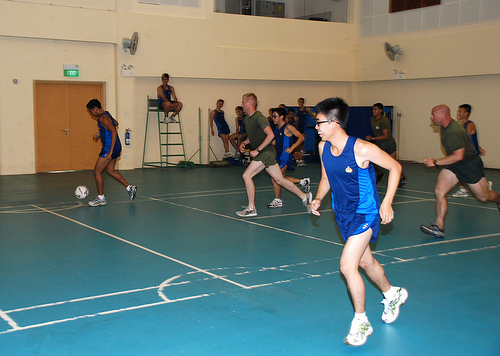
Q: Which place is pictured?
A: It is a gym.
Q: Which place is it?
A: It is a gym.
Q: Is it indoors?
A: Yes, it is indoors.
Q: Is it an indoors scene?
A: Yes, it is indoors.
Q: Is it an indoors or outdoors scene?
A: It is indoors.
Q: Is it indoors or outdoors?
A: It is indoors.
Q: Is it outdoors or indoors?
A: It is indoors.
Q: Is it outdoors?
A: No, it is indoors.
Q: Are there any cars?
A: No, there are no cars.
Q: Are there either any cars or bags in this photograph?
A: No, there are no cars or bags.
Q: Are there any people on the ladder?
A: Yes, there is a person on the ladder.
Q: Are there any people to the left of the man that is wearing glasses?
A: Yes, there is a person to the left of the man.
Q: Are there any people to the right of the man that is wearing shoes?
A: No, the person is to the left of the man.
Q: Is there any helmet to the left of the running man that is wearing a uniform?
A: No, there is a person to the left of the man.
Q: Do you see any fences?
A: No, there are no fences.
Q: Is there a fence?
A: No, there are no fences.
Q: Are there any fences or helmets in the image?
A: No, there are no fences or helmets.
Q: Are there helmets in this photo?
A: No, there are no helmets.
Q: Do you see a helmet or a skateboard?
A: No, there are no helmets or skateboards.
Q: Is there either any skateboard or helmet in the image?
A: No, there are no helmets or skateboards.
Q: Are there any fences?
A: No, there are no fences.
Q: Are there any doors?
A: Yes, there are doors.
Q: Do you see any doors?
A: Yes, there are doors.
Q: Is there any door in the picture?
A: Yes, there are doors.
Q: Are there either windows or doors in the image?
A: Yes, there are doors.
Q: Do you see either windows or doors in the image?
A: Yes, there are doors.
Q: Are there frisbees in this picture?
A: No, there are no frisbees.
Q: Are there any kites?
A: No, there are no kites.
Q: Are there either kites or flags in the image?
A: No, there are no kites or flags.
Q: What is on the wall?
A: The fan is on the wall.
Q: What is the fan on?
A: The fan is on the wall.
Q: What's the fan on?
A: The fan is on the wall.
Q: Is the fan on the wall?
A: Yes, the fan is on the wall.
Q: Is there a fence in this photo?
A: No, there are no fences.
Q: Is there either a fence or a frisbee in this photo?
A: No, there are no fences or frisbees.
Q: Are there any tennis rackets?
A: No, there are no tennis rackets.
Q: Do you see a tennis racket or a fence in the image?
A: No, there are no rackets or fences.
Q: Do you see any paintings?
A: No, there are no paintings.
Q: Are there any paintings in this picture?
A: No, there are no paintings.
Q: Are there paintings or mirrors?
A: No, there are no paintings or mirrors.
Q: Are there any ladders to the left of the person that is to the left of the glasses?
A: Yes, there is a ladder to the left of the person.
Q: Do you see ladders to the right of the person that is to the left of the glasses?
A: No, the ladder is to the left of the person.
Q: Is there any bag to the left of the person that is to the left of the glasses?
A: No, there is a ladder to the left of the person.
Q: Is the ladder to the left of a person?
A: Yes, the ladder is to the left of a person.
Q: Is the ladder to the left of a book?
A: No, the ladder is to the left of a person.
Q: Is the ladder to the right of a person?
A: No, the ladder is to the left of a person.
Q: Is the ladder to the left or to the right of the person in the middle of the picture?
A: The ladder is to the left of the person.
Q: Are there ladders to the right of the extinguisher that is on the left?
A: Yes, there is a ladder to the right of the fire extinguisher.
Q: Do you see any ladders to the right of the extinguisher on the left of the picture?
A: Yes, there is a ladder to the right of the fire extinguisher.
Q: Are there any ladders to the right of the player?
A: Yes, there is a ladder to the right of the player.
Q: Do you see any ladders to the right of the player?
A: Yes, there is a ladder to the right of the player.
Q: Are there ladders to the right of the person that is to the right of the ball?
A: Yes, there is a ladder to the right of the player.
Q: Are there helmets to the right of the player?
A: No, there is a ladder to the right of the player.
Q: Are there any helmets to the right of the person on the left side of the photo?
A: No, there is a ladder to the right of the player.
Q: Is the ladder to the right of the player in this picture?
A: Yes, the ladder is to the right of the player.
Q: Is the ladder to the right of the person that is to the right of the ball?
A: Yes, the ladder is to the right of the player.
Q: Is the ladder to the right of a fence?
A: No, the ladder is to the right of the player.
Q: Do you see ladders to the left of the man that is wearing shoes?
A: Yes, there is a ladder to the left of the man.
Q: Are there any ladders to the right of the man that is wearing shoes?
A: No, the ladder is to the left of the man.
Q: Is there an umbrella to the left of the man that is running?
A: No, there is a ladder to the left of the man.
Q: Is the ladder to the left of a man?
A: Yes, the ladder is to the left of a man.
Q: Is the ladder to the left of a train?
A: No, the ladder is to the left of a man.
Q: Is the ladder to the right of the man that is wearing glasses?
A: No, the ladder is to the left of the man.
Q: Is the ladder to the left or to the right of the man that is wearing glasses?
A: The ladder is to the left of the man.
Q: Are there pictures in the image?
A: No, there are no pictures.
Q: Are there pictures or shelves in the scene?
A: No, there are no pictures or shelves.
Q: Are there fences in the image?
A: No, there are no fences.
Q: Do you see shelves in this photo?
A: No, there are no shelves.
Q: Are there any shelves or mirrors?
A: No, there are no shelves or mirrors.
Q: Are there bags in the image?
A: No, there are no bags.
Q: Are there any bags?
A: No, there are no bags.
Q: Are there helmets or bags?
A: No, there are no bags or helmets.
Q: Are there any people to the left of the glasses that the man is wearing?
A: Yes, there is a person to the left of the glasses.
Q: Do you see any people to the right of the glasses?
A: No, the person is to the left of the glasses.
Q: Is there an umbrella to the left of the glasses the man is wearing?
A: No, there is a person to the left of the glasses.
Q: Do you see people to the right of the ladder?
A: Yes, there is a person to the right of the ladder.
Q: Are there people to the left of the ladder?
A: No, the person is to the right of the ladder.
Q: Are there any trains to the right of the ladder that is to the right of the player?
A: No, there is a person to the right of the ladder.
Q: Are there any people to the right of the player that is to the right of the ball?
A: Yes, there is a person to the right of the player.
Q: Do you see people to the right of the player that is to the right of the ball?
A: Yes, there is a person to the right of the player.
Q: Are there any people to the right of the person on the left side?
A: Yes, there is a person to the right of the player.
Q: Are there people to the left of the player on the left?
A: No, the person is to the right of the player.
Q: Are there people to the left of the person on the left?
A: No, the person is to the right of the player.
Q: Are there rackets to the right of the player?
A: No, there is a person to the right of the player.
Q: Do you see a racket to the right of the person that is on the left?
A: No, there is a person to the right of the player.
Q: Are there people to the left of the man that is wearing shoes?
A: Yes, there is a person to the left of the man.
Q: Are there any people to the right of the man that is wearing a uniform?
A: No, the person is to the left of the man.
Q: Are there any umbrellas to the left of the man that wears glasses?
A: No, there is a person to the left of the man.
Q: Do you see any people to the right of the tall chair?
A: Yes, there is a person to the right of the chair.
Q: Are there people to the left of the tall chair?
A: No, the person is to the right of the chair.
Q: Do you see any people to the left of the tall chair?
A: No, the person is to the right of the chair.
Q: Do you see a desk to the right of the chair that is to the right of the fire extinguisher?
A: No, there is a person to the right of the chair.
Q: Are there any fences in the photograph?
A: No, there are no fences.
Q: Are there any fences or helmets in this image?
A: No, there are no fences or helmets.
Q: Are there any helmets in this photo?
A: No, there are no helmets.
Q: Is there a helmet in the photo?
A: No, there are no helmets.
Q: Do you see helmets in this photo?
A: No, there are no helmets.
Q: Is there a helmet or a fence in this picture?
A: No, there are no helmets or fences.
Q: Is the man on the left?
A: No, the man is on the right of the image.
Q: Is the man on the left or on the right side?
A: The man is on the right of the image.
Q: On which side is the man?
A: The man is on the right of the image.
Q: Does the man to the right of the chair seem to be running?
A: Yes, the man is running.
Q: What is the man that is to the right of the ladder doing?
A: The man is running.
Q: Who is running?
A: The man is running.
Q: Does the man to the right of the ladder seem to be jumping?
A: No, the man is running.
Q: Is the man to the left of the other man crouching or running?
A: The man is running.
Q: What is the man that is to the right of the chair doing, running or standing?
A: The man is running.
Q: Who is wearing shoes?
A: The man is wearing shoes.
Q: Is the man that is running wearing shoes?
A: Yes, the man is wearing shoes.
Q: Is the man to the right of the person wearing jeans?
A: No, the man is wearing shoes.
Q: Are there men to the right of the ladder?
A: Yes, there is a man to the right of the ladder.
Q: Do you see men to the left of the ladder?
A: No, the man is to the right of the ladder.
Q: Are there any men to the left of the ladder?
A: No, the man is to the right of the ladder.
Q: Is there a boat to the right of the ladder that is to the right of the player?
A: No, there is a man to the right of the ladder.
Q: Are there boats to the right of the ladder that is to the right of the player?
A: No, there is a man to the right of the ladder.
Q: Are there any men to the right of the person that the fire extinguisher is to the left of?
A: Yes, there is a man to the right of the person.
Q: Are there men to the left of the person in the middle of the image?
A: No, the man is to the right of the person.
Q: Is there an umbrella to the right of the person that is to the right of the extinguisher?
A: No, there is a man to the right of the person.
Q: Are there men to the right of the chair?
A: Yes, there is a man to the right of the chair.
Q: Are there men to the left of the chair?
A: No, the man is to the right of the chair.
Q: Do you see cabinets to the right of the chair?
A: No, there is a man to the right of the chair.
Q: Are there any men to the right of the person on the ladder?
A: Yes, there is a man to the right of the person.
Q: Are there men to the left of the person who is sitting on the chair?
A: No, the man is to the right of the person.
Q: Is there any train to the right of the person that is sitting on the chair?
A: No, there is a man to the right of the person.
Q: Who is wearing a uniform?
A: The man is wearing a uniform.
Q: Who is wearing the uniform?
A: The man is wearing a uniform.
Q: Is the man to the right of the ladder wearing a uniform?
A: Yes, the man is wearing a uniform.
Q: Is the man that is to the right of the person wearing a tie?
A: No, the man is wearing a uniform.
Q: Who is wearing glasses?
A: The man is wearing glasses.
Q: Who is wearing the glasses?
A: The man is wearing glasses.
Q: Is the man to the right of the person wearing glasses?
A: Yes, the man is wearing glasses.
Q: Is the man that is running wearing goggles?
A: No, the man is wearing glasses.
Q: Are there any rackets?
A: No, there are no rackets.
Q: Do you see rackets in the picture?
A: No, there are no rackets.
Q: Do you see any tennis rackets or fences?
A: No, there are no tennis rackets or fences.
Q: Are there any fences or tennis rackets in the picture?
A: No, there are no tennis rackets or fences.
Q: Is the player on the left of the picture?
A: Yes, the player is on the left of the image.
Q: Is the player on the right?
A: No, the player is on the left of the image.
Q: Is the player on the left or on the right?
A: The player is on the left of the image.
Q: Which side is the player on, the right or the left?
A: The player is on the left of the image.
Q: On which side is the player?
A: The player is on the left of the image.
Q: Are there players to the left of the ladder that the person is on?
A: Yes, there is a player to the left of the ladder.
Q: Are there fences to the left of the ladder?
A: No, there is a player to the left of the ladder.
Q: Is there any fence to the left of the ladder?
A: No, there is a player to the left of the ladder.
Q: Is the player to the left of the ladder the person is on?
A: Yes, the player is to the left of the ladder.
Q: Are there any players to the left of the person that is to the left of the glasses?
A: Yes, there is a player to the left of the person.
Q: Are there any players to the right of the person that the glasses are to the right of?
A: No, the player is to the left of the person.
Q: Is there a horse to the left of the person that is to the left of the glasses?
A: No, there is a player to the left of the person.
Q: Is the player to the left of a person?
A: Yes, the player is to the left of a person.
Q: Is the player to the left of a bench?
A: No, the player is to the left of a person.